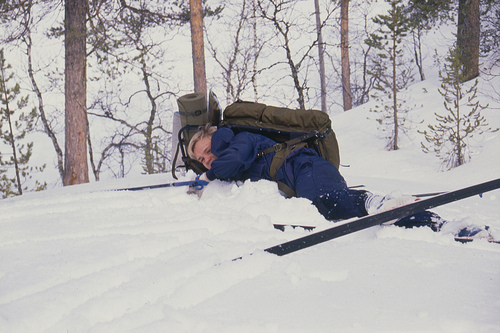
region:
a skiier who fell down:
[28, 28, 459, 315]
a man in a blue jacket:
[191, 111, 339, 208]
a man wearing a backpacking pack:
[153, 60, 342, 203]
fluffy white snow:
[44, 210, 181, 310]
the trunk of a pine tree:
[27, 19, 124, 188]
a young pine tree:
[417, 44, 499, 181]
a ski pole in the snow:
[87, 175, 214, 203]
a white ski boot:
[358, 183, 431, 238]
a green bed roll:
[160, 87, 220, 132]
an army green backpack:
[225, 82, 412, 159]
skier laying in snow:
[148, 86, 474, 251]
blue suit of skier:
[216, 125, 401, 231]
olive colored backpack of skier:
[180, 84, 342, 170]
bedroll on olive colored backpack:
[173, 96, 220, 163]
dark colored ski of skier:
[270, 176, 497, 273]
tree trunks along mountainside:
[8, 14, 498, 181]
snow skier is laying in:
[88, 134, 499, 291]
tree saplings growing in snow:
[368, 17, 491, 169]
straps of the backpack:
[239, 130, 302, 190]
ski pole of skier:
[106, 171, 208, 196]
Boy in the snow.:
[145, 97, 495, 242]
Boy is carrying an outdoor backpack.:
[191, 95, 356, 154]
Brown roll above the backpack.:
[166, 84, 211, 179]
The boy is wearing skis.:
[236, 182, 498, 283]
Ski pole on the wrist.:
[99, 173, 224, 200]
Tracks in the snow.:
[58, 237, 241, 332]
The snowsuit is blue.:
[201, 137, 363, 210]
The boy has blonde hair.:
[184, 125, 218, 157]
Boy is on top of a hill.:
[33, 70, 498, 304]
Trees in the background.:
[3, 1, 498, 163]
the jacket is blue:
[195, 128, 335, 230]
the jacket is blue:
[189, 104, 276, 206]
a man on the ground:
[140, 65, 411, 307]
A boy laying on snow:
[181, 122, 475, 252]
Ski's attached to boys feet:
[188, 195, 482, 268]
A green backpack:
[228, 95, 342, 154]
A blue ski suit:
[208, 128, 352, 213]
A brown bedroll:
[170, 91, 234, 131]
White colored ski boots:
[367, 188, 422, 223]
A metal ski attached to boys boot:
[265, 182, 497, 262]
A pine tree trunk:
[45, 11, 103, 201]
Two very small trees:
[372, 18, 475, 169]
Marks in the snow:
[74, 202, 224, 309]